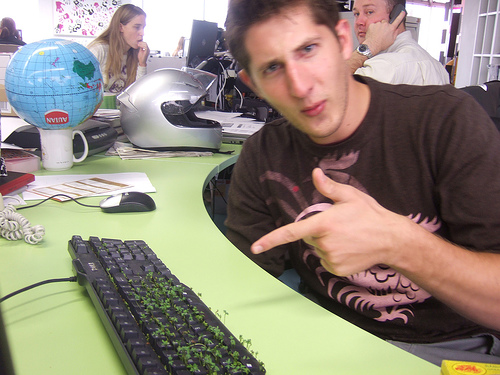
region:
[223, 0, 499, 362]
man pointing at a keyboard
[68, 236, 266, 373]
a black keyboard with green sprouts on it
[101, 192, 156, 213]
a wired black and silver computer mouse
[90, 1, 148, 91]
a woman with long blonde hair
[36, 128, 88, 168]
a white mug on a green desk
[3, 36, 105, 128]
a terrestrial globe on a white mug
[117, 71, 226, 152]
a silver motorcycle helmet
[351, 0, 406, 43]
man holding a phone to his ear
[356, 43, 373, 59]
man wearing a silver watch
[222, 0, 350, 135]
man with short brown hair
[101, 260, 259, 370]
grass is on the keyboard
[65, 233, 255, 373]
the keyboard is black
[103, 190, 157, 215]
the mouse is black and grey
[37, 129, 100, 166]
the cup is white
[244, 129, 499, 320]
the shirt is brown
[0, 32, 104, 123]
the world is on the cup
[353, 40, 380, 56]
watch is on the wrist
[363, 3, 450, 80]
the man is on the phone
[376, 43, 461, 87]
the shirt is white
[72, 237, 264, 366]
a black keyboard with some greenery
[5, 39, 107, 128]
a globe of the earth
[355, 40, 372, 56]
a silver watch with a black face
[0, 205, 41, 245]
a twisted white phone cord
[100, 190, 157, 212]
a black and white computer mouse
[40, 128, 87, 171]
a white coffee cup with decoration on it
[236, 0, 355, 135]
a young man's face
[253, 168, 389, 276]
a hand with a finger and thumb extended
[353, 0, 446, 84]
a man in a white shirt looking over his shoulder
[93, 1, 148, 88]
a young girl with her hand to her face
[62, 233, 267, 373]
computer keyboard with green plants growing on it.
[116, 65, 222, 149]
silver helmet with clear face shield.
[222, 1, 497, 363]
young man pointing at keyboard on desk.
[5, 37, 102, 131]
globe sitting in white coffee mug.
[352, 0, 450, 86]
man holding phone looking over shoulder.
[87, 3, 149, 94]
girl with hand to mouth viewing monitor.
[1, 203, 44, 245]
tangled phone cord laying on desk top.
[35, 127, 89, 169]
white coffee mug with large handle.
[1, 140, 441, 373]
curved desk top with a wide variety of items on it.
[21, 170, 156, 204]
white sheet of paper under a smaller brown and white paper.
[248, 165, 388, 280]
the hand of a man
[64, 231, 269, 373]
a black computer keyboard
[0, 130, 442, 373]
a green desk top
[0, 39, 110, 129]
a blue globe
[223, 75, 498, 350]
a man's brown shirt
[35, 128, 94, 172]
a large white coffee mug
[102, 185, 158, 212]
a black computer mouse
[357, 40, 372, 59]
a man's gray wristwatch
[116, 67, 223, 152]
a large gray helmet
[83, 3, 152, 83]
a woman's long blonde hair